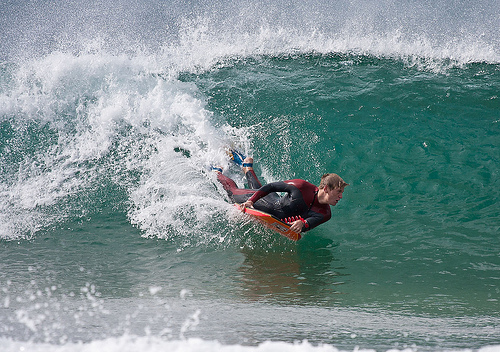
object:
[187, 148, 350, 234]
man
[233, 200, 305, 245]
surf board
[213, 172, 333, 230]
wet suit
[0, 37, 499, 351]
water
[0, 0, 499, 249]
waves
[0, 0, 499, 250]
foam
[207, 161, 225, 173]
footstraps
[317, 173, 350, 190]
hair